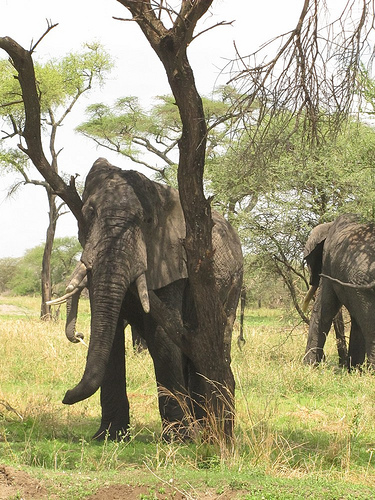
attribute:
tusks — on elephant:
[42, 288, 83, 303]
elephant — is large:
[64, 158, 244, 438]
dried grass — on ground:
[341, 377, 367, 409]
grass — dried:
[3, 400, 373, 499]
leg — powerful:
[91, 321, 136, 442]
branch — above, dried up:
[198, 0, 329, 148]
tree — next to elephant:
[120, 6, 246, 444]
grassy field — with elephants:
[6, 316, 369, 397]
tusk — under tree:
[132, 272, 155, 312]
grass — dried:
[0, 288, 374, 499]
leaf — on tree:
[0, 38, 120, 326]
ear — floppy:
[301, 219, 335, 259]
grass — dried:
[273, 375, 364, 462]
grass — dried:
[233, 341, 372, 469]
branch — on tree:
[60, 36, 233, 141]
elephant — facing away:
[299, 218, 374, 374]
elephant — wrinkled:
[62, 161, 242, 412]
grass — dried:
[5, 322, 372, 497]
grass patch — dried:
[283, 396, 343, 425]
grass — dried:
[4, 292, 373, 385]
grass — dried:
[240, 362, 357, 442]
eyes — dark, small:
[76, 208, 146, 233]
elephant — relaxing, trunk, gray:
[45, 156, 249, 446]